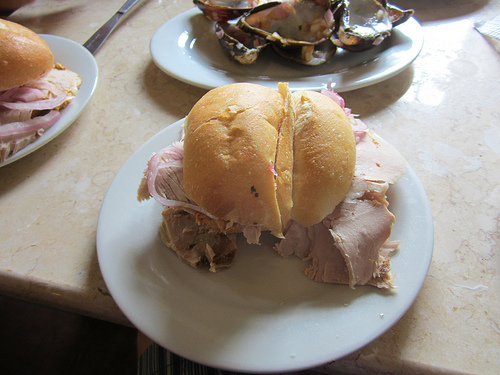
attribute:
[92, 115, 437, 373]
plate — white, round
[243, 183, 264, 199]
spot — dark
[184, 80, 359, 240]
bread — brown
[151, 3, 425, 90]
plate — round , white 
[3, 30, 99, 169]
plate — white 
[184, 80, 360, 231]
sandwich roll — tan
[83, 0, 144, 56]
butter knife — silver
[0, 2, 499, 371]
table — cream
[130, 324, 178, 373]
leg — silver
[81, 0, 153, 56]
knife — silver 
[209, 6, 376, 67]
shell — brown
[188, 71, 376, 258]
bun — brown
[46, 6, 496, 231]
table — beige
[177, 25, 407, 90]
shadows — dark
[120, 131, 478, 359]
plate — white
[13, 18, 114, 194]
plate — white